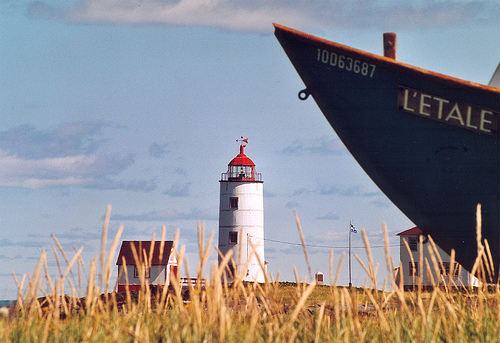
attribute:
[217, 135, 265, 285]
light house — white 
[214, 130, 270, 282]
lighthouse — white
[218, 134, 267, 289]
light tower — white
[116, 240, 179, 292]
red building — white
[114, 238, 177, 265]
roof — red 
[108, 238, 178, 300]
building — small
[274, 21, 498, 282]
boat — blue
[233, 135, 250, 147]
weather vane — red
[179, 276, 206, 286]
fence — red, wooden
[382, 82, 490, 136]
text — L'Etale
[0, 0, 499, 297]
sky — mostly clear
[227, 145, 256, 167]
roof — red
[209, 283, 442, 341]
grass — dry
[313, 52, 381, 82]
number — white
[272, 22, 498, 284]
bow — boat's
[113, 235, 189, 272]
roof — red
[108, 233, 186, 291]
building — small